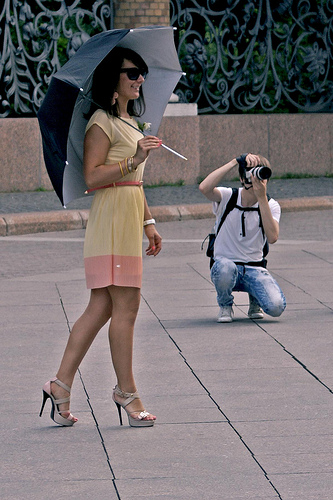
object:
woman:
[45, 46, 157, 429]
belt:
[83, 179, 144, 195]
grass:
[272, 168, 331, 179]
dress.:
[83, 108, 150, 295]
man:
[197, 145, 290, 324]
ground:
[0, 174, 333, 499]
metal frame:
[0, 1, 332, 118]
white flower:
[140, 119, 153, 133]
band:
[143, 217, 156, 227]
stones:
[166, 189, 195, 198]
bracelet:
[115, 160, 126, 180]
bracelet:
[124, 156, 130, 177]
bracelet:
[126, 155, 134, 175]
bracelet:
[131, 153, 136, 172]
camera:
[237, 149, 273, 188]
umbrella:
[36, 20, 193, 209]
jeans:
[210, 255, 286, 317]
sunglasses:
[118, 64, 150, 79]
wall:
[1, 115, 333, 180]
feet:
[43, 380, 79, 424]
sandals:
[109, 376, 157, 431]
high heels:
[36, 376, 79, 429]